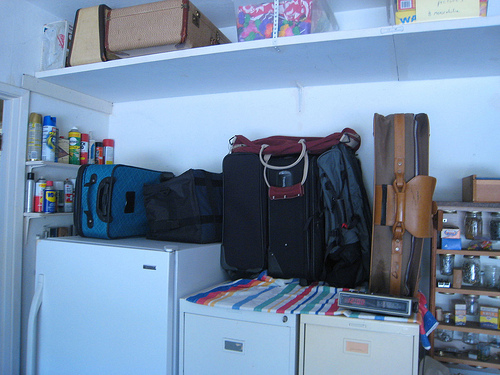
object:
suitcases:
[265, 154, 314, 277]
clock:
[338, 290, 412, 317]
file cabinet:
[298, 312, 419, 375]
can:
[35, 176, 47, 213]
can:
[25, 166, 39, 213]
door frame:
[0, 84, 18, 372]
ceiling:
[0, 0, 250, 27]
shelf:
[25, 161, 82, 174]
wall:
[112, 91, 259, 126]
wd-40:
[47, 192, 57, 197]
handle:
[224, 340, 243, 352]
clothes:
[232, 1, 340, 42]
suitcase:
[220, 152, 266, 278]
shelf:
[33, 16, 500, 80]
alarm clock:
[337, 287, 420, 317]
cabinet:
[298, 314, 420, 375]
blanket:
[185, 270, 437, 350]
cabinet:
[177, 296, 297, 375]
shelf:
[434, 248, 499, 256]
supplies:
[435, 211, 500, 364]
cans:
[87, 131, 95, 165]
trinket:
[479, 239, 492, 251]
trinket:
[468, 243, 479, 250]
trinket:
[438, 281, 451, 288]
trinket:
[444, 312, 452, 324]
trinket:
[480, 271, 487, 288]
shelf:
[436, 322, 499, 335]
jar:
[463, 294, 480, 315]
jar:
[463, 255, 482, 284]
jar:
[439, 254, 455, 276]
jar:
[481, 264, 500, 288]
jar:
[464, 210, 482, 239]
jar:
[487, 211, 500, 241]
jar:
[437, 209, 462, 250]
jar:
[451, 299, 466, 327]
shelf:
[435, 287, 492, 295]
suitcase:
[105, 0, 231, 57]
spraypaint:
[26, 112, 42, 162]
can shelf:
[102, 139, 114, 166]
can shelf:
[80, 133, 89, 165]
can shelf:
[41, 115, 56, 162]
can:
[53, 181, 65, 212]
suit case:
[220, 154, 268, 281]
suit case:
[267, 152, 326, 286]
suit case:
[316, 142, 372, 288]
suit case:
[367, 113, 437, 299]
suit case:
[73, 163, 177, 239]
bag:
[228, 127, 362, 200]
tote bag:
[72, 163, 176, 240]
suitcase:
[315, 141, 372, 288]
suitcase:
[367, 113, 435, 299]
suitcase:
[142, 168, 222, 243]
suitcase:
[72, 163, 176, 240]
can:
[26, 112, 42, 161]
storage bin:
[235, 1, 340, 43]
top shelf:
[30, 0, 500, 80]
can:
[63, 177, 74, 212]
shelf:
[23, 212, 85, 244]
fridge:
[20, 234, 219, 375]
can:
[42, 180, 56, 213]